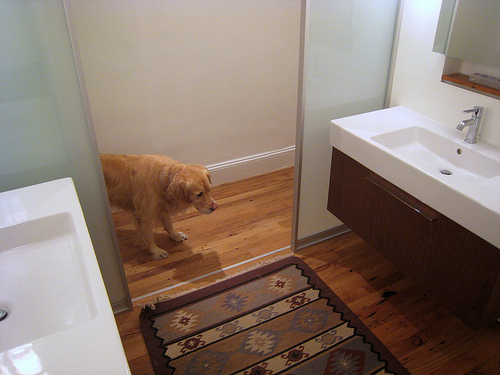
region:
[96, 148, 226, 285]
a dog standing in the hallway.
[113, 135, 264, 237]
a dog looking inside a bathroom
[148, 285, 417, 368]
a brown rug laying on the floor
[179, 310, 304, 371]
a brown rug decorated in designs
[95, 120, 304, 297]
a dog standing next to a bathroom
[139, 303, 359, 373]
a rug near a doorway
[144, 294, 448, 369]
a rug located in the bathroom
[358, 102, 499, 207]
a vanity with a square sink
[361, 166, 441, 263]
a vanity displaying a silver handle.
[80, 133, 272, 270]
a hallway with a dog standing.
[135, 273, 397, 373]
The rug is on the bathroom floor.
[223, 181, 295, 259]
The floor is made out of wood.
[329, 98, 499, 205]
The sink is white.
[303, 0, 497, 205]
The sink is next to the glass door.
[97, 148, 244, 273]
The dog is standing on the wood floor.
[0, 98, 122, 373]
The glass door is next to the bathtub.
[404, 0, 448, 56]
The bathroom light is turned on.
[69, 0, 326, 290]
The bathroom door is open.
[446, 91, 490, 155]
The faucet is silver colored.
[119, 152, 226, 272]
The front part of the dog is seen.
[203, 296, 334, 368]
rug on the bathroom floor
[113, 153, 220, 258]
dog standing on the wood floor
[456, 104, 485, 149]
chrome bathroom sink faucet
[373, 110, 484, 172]
white bathroom sink with a silver faucet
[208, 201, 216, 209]
dog's nose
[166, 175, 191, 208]
dog's floppy ear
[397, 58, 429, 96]
white bathroom wall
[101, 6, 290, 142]
white wall behind the dog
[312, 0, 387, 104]
white frosted glass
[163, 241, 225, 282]
dog's shadow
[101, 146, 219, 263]
one medium sized light brown dog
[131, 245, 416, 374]
one brown patterned rectangular throw rug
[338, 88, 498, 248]
one rectangular bathroom sink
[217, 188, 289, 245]
light brown hardwood floor boards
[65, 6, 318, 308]
dog standing in bathroom doorway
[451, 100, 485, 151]
shiny chrome metal bathroom faucet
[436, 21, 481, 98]
corner of square shaped bathroom mirror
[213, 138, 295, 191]
section of household white baseboard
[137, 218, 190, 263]
two front dog legs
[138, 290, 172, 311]
bit of beige floor rug tassels